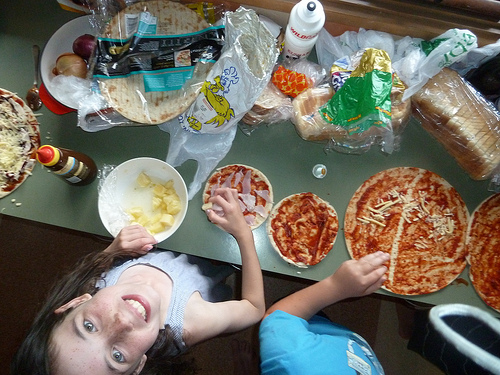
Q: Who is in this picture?
A: A little girl with another girl/boy next to her.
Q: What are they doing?
A: Making pizza.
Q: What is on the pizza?
A: Tomato sauce and cheese.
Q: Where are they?
A: In a kitchen.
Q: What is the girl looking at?
A: The camera.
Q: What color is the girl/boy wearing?
A: Blue.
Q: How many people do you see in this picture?
A: Two.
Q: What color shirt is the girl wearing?
A: Gray.